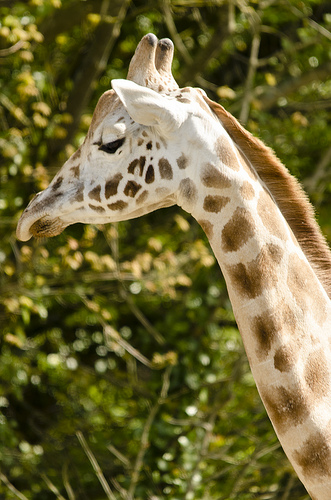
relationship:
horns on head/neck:
[94, 25, 180, 75] [14, 30, 213, 245]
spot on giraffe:
[270, 351, 302, 373] [52, 104, 234, 221]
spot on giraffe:
[248, 365, 319, 423] [48, 113, 240, 226]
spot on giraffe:
[196, 189, 236, 218] [96, 95, 286, 265]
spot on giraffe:
[253, 179, 287, 257] [35, 62, 288, 304]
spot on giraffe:
[222, 177, 250, 213] [18, 89, 257, 221]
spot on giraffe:
[211, 216, 287, 280] [73, 131, 268, 232]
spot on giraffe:
[40, 169, 65, 192] [49, 81, 224, 261]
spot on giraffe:
[137, 139, 158, 154] [31, 86, 254, 256]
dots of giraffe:
[101, 172, 177, 209] [38, 53, 316, 396]